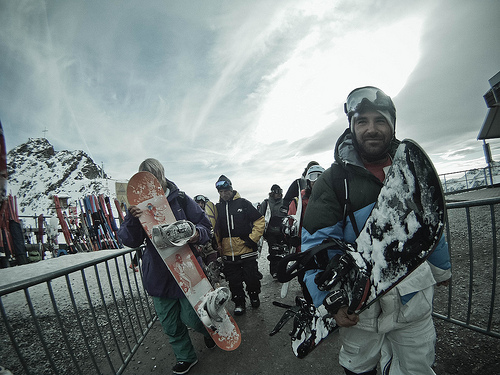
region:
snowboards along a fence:
[5, 192, 127, 251]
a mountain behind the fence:
[6, 130, 120, 214]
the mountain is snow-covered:
[6, 127, 131, 214]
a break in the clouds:
[250, 6, 445, 146]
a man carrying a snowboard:
[289, 82, 456, 374]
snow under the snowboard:
[281, 149, 415, 350]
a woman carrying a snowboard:
[117, 153, 247, 368]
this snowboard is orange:
[116, 164, 248, 354]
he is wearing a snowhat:
[340, 83, 398, 148]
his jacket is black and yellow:
[204, 187, 267, 256]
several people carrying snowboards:
[106, 76, 466, 371]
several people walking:
[119, 81, 454, 373]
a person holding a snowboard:
[115, 155, 220, 371]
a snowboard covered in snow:
[290, 135, 446, 371]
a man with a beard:
[340, 83, 400, 163]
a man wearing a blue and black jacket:
[298, 80, 458, 310]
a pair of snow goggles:
[343, 85, 394, 115]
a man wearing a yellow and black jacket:
[202, 170, 267, 267]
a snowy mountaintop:
[7, 125, 106, 189]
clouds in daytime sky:
[1, 1, 496, 195]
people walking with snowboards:
[119, 84, 446, 374]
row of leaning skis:
[2, 194, 124, 252]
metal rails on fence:
[0, 250, 148, 373]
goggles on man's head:
[341, 84, 394, 118]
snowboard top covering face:
[128, 172, 242, 350]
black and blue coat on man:
[300, 150, 450, 302]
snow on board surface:
[289, 142, 448, 359]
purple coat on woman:
[120, 188, 211, 298]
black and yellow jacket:
[215, 193, 267, 263]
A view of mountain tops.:
[3, 121, 108, 190]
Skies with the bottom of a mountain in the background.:
[1, 194, 121, 264]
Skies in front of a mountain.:
[0, 122, 121, 258]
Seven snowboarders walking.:
[113, 83, 458, 374]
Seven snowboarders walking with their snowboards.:
[114, 84, 448, 374]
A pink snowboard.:
[125, 171, 244, 352]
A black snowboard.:
[287, 139, 451, 358]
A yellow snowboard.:
[203, 199, 225, 258]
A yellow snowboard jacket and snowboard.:
[205, 175, 267, 257]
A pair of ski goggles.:
[330, 89, 394, 124]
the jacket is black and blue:
[301, 173, 458, 298]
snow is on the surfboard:
[355, 185, 426, 272]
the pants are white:
[358, 318, 438, 373]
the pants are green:
[152, 301, 212, 353]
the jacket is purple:
[112, 203, 222, 304]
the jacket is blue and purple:
[216, 198, 273, 257]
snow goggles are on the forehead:
[333, 86, 400, 122]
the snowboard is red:
[121, 175, 261, 357]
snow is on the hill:
[21, 140, 99, 210]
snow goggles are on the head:
[210, 179, 237, 190]